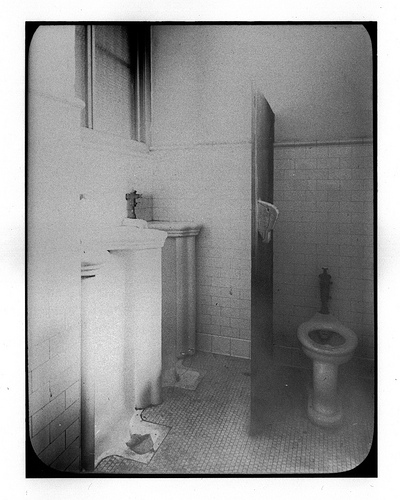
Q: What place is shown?
A: It is a restroom.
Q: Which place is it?
A: It is a restroom.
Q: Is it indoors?
A: Yes, it is indoors.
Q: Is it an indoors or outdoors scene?
A: It is indoors.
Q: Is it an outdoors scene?
A: No, it is indoors.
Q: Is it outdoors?
A: No, it is indoors.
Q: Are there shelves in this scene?
A: No, there are no shelves.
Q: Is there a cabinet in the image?
A: No, there are no cabinets.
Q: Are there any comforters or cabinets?
A: No, there are no cabinets or comforters.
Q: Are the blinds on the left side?
A: Yes, the blinds are on the left of the image.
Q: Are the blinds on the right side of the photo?
A: No, the blinds are on the left of the image.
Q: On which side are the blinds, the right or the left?
A: The blinds are on the left of the image.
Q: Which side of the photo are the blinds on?
A: The blinds are on the left of the image.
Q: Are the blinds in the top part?
A: Yes, the blinds are in the top of the image.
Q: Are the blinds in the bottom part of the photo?
A: No, the blinds are in the top of the image.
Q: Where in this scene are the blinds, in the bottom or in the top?
A: The blinds are in the top of the image.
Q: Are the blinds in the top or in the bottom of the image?
A: The blinds are in the top of the image.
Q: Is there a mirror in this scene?
A: No, there are no mirrors.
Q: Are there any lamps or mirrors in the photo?
A: No, there are no mirrors or lamps.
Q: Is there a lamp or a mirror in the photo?
A: No, there are no mirrors or lamps.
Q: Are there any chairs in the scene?
A: No, there are no chairs.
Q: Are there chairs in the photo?
A: No, there are no chairs.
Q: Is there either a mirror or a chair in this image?
A: No, there are no chairs or mirrors.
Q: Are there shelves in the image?
A: No, there are no shelves.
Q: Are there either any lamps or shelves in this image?
A: No, there are no shelves or lamps.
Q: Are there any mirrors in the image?
A: No, there are no mirrors.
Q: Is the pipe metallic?
A: Yes, the pipe is metallic.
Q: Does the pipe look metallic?
A: Yes, the pipe is metallic.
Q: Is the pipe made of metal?
A: Yes, the pipe is made of metal.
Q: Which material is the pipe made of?
A: The pipe is made of metal.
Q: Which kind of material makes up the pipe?
A: The pipe is made of metal.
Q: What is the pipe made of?
A: The pipe is made of metal.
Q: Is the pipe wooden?
A: No, the pipe is metallic.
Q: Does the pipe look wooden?
A: No, the pipe is metallic.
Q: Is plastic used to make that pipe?
A: No, the pipe is made of metal.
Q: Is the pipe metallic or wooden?
A: The pipe is metallic.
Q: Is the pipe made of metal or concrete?
A: The pipe is made of metal.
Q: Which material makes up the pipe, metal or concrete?
A: The pipe is made of metal.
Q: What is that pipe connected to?
A: The pipe is connected to the wall.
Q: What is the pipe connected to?
A: The pipe is connected to the wall.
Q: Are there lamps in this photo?
A: No, there are no lamps.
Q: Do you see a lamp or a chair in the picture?
A: No, there are no lamps or chairs.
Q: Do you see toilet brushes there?
A: No, there are no toilet brushes.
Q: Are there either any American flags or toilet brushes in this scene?
A: No, there are no toilet brushes or American flags.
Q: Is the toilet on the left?
A: No, the toilet is on the right of the image.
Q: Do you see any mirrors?
A: No, there are no mirrors.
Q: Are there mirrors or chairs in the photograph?
A: No, there are no mirrors or chairs.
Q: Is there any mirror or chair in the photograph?
A: No, there are no mirrors or chairs.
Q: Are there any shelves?
A: No, there are no shelves.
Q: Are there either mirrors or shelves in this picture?
A: No, there are no shelves or mirrors.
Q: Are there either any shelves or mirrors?
A: No, there are no shelves or mirrors.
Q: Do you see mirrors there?
A: No, there are no mirrors.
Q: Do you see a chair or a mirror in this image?
A: No, there are no mirrors or chairs.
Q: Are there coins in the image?
A: No, there are no coins.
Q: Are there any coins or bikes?
A: No, there are no coins or bikes.